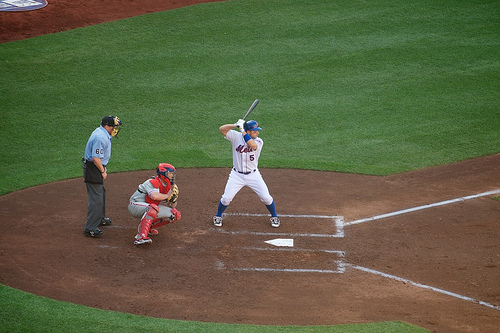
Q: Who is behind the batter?
A: The catcher.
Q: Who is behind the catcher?
A: The umpire.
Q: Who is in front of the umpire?
A: The catcher.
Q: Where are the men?
A: In a baseball field.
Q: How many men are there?
A: Three.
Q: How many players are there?
A: Two.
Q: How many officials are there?
A: One.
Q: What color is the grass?
A: Green.